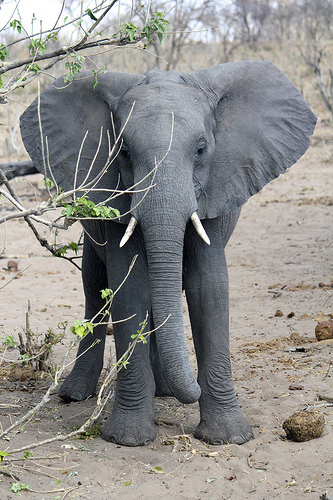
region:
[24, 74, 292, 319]
the elephant has tusks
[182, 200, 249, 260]
the tusk is white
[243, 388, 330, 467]
a ball of poop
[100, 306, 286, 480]
the elephant's feet are grey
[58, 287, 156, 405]
leaves on the tree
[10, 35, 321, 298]
the elephant has big ears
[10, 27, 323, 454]
the elephant is small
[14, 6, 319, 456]
this elephant is young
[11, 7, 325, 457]
this is an african elephant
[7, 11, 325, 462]
the species is elephant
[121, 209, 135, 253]
The tusk on the left side of the elephant's trunk.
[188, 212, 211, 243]
The tusk on the right side of the elephant's trunk.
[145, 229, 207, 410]
The trunk of the elephant.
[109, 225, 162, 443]
The left front leg of the elephant.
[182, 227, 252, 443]
The right front leg of the elephant.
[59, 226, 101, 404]
The back left leg of the elephant.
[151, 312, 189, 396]
The back right leg of the elephant.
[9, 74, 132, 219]
The large left ear of the elephant.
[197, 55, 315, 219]
The large right ear of the elephant.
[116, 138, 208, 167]
The eyes of the elephant standing.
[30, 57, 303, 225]
The elephant has large ears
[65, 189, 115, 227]
The leaf is green.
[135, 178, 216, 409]
The trunk is long.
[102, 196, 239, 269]
His tusks are white.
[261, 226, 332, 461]
The ground is dusty.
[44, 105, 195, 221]
The elephant is grey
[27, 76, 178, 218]
The sticks are bare.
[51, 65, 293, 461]
The elephant is standing.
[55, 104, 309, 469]
The elephant is outside.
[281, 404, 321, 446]
The rock is large.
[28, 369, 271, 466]
elephant feet on the ground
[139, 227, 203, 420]
trunk of an elephant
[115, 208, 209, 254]
tusks of an elephant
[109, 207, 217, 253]
white tusks of an elephant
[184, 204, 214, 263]
pointy tusk of an elephant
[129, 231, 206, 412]
huge trunk of an elephant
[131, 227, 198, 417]
powerful trunk of an elephant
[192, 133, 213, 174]
left eye of an elephant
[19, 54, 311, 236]
head of an elephant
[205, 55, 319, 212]
big left ear of an elephant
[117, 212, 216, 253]
The elephants tusks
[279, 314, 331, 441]
The large pieces of elephant dung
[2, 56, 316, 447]
The large, grey elephant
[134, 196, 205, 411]
The trunk of the elephant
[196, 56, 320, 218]
The elephant's left ear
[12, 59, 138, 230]
The right ear of the elephant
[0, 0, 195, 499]
The geen leaves of a tree in front of elephant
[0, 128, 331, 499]
The dirt field the elephant is on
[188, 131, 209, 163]
The elephant's left eye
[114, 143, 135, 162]
The elephants right eye